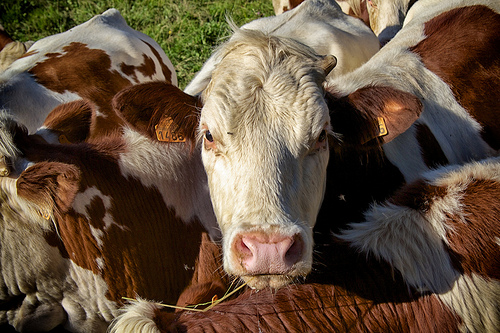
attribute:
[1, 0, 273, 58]
green grass — on the ground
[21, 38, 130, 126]
skin — brown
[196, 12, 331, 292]
fur — white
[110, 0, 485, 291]
cow — looking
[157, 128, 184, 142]
writing — black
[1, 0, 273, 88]
grass — green